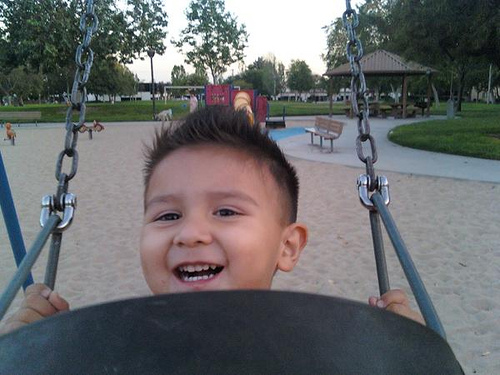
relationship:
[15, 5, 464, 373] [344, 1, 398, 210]
swing has chain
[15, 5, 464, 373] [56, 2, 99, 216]
swing has chain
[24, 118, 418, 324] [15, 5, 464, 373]
boy on swing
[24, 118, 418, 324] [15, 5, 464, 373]
boy holds swing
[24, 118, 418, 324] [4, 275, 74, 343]
boy has hand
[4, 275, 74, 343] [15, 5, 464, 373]
hand on swing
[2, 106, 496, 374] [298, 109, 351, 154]
playground has bench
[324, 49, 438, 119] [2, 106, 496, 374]
shelter behind playground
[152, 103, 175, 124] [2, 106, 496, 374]
dog in playground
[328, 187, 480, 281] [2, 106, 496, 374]
sand on playground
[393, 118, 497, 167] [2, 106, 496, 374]
grassy area in playground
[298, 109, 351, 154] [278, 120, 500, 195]
bench on sidewalk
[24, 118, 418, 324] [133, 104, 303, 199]
boy has hair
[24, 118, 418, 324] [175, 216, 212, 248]
boy has nose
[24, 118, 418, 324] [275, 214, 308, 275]
boy has ear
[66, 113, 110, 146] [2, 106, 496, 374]
rocking horse on playground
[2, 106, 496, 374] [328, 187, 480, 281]
playground has sand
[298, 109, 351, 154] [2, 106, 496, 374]
bench on playground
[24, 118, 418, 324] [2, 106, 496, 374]
boy in playground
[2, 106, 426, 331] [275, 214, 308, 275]
boy has ear